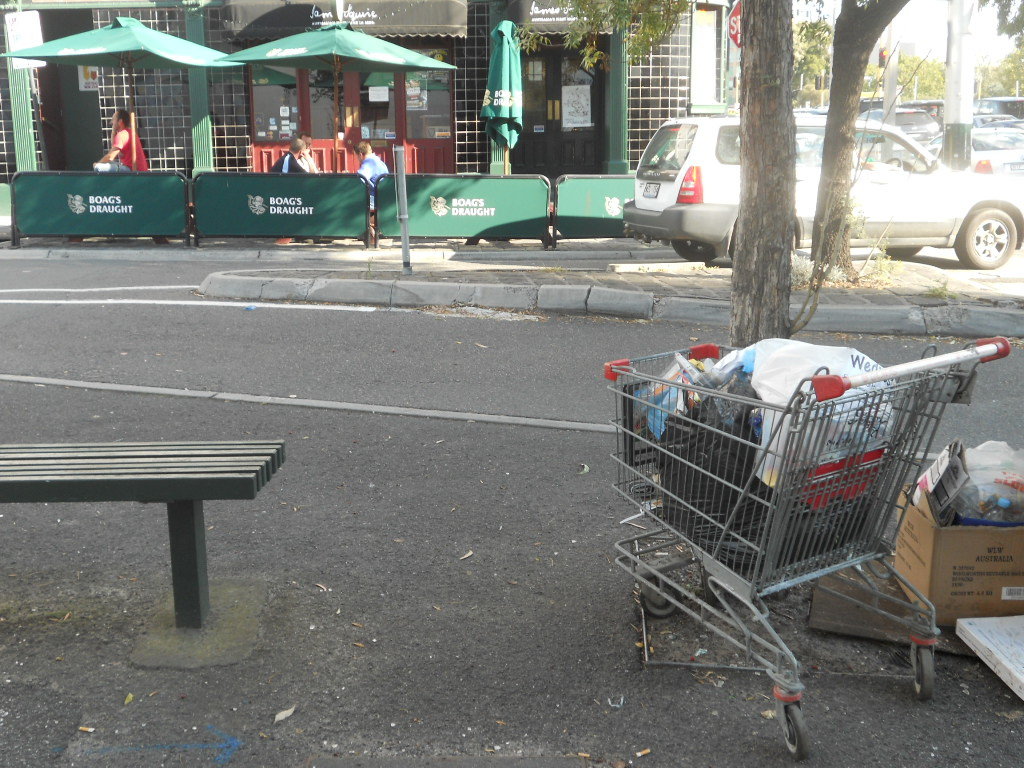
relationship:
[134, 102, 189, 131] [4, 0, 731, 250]
window on building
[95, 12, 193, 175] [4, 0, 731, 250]
window on building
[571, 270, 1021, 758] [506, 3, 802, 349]
cart near tree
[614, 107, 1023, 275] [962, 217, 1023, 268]
automobile has wheel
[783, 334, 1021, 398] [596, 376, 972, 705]
handle rests on shopping cart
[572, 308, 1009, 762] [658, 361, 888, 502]
cart holds merchandise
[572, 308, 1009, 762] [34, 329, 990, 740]
cart rests on pavement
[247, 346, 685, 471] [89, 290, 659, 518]
line painted on road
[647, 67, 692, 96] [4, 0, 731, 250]
window on building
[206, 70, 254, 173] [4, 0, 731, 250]
window on building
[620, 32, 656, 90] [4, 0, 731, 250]
window on building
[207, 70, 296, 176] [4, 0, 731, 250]
window on building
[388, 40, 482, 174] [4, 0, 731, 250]
window on building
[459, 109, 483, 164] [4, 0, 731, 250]
window on building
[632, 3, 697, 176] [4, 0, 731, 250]
window on building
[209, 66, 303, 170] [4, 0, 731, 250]
window on building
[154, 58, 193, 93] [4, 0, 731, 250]
window on building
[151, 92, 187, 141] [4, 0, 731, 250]
window on building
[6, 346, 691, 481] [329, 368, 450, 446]
view of lines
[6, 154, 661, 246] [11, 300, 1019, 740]
green barrier near road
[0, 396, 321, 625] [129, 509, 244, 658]
bench has bench leg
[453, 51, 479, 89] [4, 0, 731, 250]
window on building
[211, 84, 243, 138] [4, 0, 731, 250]
window on building